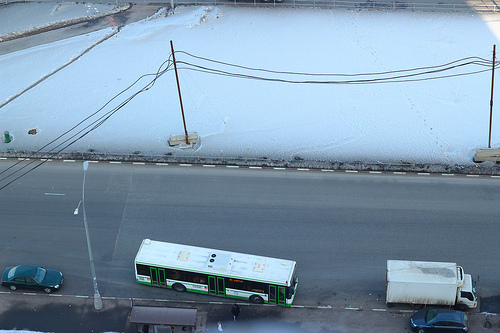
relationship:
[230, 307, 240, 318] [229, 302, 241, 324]
jacket on person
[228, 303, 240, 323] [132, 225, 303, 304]
person near bus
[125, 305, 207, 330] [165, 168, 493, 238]
building along road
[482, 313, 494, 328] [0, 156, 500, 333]
person along pavement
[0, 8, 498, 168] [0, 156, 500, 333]
snow near pavement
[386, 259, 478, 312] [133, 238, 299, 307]
truck in front of bus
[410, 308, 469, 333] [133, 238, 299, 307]
blue car in front of bus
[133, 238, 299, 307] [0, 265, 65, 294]
bus in front of car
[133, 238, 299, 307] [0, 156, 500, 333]
bus in street pavement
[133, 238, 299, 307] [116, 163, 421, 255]
bus in street street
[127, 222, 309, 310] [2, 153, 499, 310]
bus in street street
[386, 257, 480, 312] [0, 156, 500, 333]
truck in street pavement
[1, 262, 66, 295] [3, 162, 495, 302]
car in street street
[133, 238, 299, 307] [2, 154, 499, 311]
bus in street road